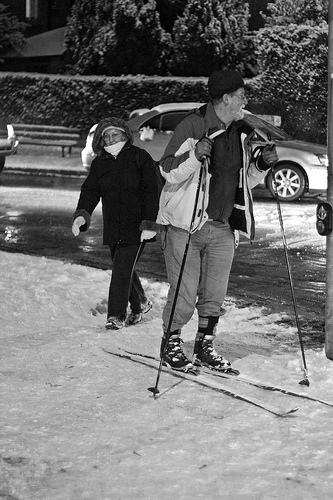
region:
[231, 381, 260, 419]
edge of a boar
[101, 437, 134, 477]
part of a ground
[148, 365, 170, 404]
part of a hooker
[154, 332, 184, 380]
part of a hooker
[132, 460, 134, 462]
part of a ground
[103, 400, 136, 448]
part of a ground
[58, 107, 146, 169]
this is a person`s head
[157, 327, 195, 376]
this is a shoe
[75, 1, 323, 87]
these are trees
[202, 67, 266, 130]
this is a person`s head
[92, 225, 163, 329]
this is a leg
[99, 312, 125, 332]
this is a shoe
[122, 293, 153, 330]
this is a shoe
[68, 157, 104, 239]
this is a hand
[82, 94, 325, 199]
this is a car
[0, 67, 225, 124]
this is a fence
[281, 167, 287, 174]
white spokes on rim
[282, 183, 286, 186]
white spokes on rim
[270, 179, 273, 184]
white spokes on rim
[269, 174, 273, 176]
white spokes on rim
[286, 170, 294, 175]
white spokes on rim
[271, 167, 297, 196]
white spokes on rim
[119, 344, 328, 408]
ski with snow on it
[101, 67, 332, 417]
A man wearing a pair of skis.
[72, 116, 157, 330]
A woman walking behind the man.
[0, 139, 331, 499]
Snow and ice on the ground.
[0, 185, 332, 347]
An icy paved road.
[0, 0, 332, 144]
Snow on the limbs of bushes and trees.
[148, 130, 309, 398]
Ski poles in the man's hands.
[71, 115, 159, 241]
The woman is wearing a dark coat with a hood.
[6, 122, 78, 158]
A park bench covered in icy snow.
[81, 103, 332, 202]
A parked car with snow on the trunk and roof.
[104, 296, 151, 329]
Tennis shoes on the woman's feet.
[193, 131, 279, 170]
the man is wearing gloves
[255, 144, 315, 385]
the man is holding a ski pole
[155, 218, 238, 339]
the man is wearing long pants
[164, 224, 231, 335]
the pants are grey in tone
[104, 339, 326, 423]
the skis are in the snow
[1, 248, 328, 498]
the snow is on the street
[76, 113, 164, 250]
the woman is wearing a coat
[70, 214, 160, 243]
the woman is wearing gloves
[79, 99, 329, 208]
the car is parked in the street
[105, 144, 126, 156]
a white paper face mask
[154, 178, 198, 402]
a black ski pole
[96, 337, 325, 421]
a pair of black skis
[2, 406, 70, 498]
clods of snow on the ground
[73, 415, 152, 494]
clods of snow on the ground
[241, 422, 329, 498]
clods of snow on the ground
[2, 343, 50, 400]
clods of snow on the ground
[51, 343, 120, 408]
clods of snow on the ground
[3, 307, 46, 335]
clods of snow on the ground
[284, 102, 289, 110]
frosty leaf behind the car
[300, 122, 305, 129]
frosty leaf behind the car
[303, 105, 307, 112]
frosty leaf behind the car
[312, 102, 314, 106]
frosty leaf behind the car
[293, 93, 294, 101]
frosty leaf behind the car